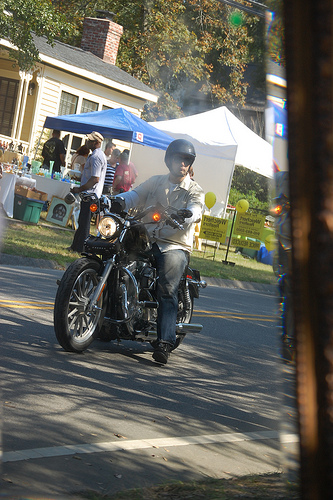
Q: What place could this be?
A: It is a yard.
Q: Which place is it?
A: It is a yard.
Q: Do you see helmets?
A: Yes, there is a helmet.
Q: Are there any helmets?
A: Yes, there is a helmet.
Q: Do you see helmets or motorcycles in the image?
A: Yes, there is a helmet.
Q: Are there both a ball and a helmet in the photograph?
A: No, there is a helmet but no balls.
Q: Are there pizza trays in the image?
A: No, there are no pizza trays.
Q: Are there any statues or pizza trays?
A: No, there are no pizza trays or statues.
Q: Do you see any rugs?
A: No, there are no rugs.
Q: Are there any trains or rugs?
A: No, there are no rugs or trains.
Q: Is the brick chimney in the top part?
A: Yes, the chimney is in the top of the image.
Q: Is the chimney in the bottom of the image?
A: No, the chimney is in the top of the image.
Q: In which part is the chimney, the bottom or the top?
A: The chimney is in the top of the image.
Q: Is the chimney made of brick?
A: Yes, the chimney is made of brick.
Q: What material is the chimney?
A: The chimney is made of brick.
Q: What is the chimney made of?
A: The chimney is made of brick.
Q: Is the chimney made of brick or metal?
A: The chimney is made of brick.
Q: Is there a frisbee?
A: No, there are no frisbees.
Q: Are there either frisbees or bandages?
A: No, there are no frisbees or bandages.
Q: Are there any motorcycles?
A: Yes, there is a motorcycle.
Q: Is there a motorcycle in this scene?
A: Yes, there is a motorcycle.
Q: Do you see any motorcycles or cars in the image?
A: Yes, there is a motorcycle.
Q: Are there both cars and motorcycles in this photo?
A: No, there is a motorcycle but no cars.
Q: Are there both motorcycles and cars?
A: No, there is a motorcycle but no cars.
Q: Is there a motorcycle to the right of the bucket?
A: Yes, there is a motorcycle to the right of the bucket.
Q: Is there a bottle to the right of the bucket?
A: No, there is a motorcycle to the right of the bucket.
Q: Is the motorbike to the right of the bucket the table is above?
A: Yes, the motorbike is to the right of the bucket.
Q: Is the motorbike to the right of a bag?
A: No, the motorbike is to the right of the bucket.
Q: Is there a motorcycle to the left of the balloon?
A: Yes, there is a motorcycle to the left of the balloon.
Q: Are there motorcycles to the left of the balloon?
A: Yes, there is a motorcycle to the left of the balloon.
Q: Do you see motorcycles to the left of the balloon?
A: Yes, there is a motorcycle to the left of the balloon.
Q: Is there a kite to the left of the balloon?
A: No, there is a motorcycle to the left of the balloon.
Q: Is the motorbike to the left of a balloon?
A: Yes, the motorbike is to the left of a balloon.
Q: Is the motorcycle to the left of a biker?
A: No, the motorcycle is to the left of a balloon.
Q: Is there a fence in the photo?
A: No, there are no fences.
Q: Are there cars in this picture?
A: No, there are no cars.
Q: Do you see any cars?
A: No, there are no cars.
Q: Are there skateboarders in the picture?
A: No, there are no skateboarders.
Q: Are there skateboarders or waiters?
A: No, there are no skateboarders or waiters.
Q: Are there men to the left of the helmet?
A: Yes, there is a man to the left of the helmet.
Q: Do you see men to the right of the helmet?
A: No, the man is to the left of the helmet.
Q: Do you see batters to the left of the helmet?
A: No, there is a man to the left of the helmet.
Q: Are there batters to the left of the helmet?
A: No, there is a man to the left of the helmet.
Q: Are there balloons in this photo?
A: Yes, there is a balloon.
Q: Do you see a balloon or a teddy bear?
A: Yes, there is a balloon.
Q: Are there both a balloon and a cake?
A: No, there is a balloon but no cakes.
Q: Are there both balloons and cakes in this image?
A: No, there is a balloon but no cakes.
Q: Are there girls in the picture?
A: No, there are no girls.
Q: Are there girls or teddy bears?
A: No, there are no girls or teddy bears.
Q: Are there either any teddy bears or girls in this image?
A: No, there are no girls or teddy bears.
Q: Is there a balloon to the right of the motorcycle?
A: Yes, there is a balloon to the right of the motorcycle.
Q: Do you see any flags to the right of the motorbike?
A: No, there is a balloon to the right of the motorbike.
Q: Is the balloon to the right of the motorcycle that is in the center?
A: Yes, the balloon is to the right of the motorbike.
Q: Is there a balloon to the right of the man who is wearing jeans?
A: Yes, there is a balloon to the right of the man.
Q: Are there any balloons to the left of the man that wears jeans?
A: No, the balloon is to the right of the man.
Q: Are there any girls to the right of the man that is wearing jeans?
A: No, there is a balloon to the right of the man.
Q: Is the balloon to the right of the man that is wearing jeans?
A: Yes, the balloon is to the right of the man.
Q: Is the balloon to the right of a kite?
A: No, the balloon is to the right of the man.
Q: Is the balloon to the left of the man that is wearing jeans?
A: No, the balloon is to the right of the man.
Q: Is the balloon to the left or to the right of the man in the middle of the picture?
A: The balloon is to the right of the man.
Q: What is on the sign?
A: The balloon is on the sign.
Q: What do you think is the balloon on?
A: The balloon is on the sign.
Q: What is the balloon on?
A: The balloon is on the sign.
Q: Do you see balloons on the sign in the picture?
A: Yes, there is a balloon on the sign.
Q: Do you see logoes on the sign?
A: No, there is a balloon on the sign.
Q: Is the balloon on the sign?
A: Yes, the balloon is on the sign.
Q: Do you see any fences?
A: No, there are no fences.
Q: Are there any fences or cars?
A: No, there are no fences or cars.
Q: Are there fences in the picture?
A: No, there are no fences.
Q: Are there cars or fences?
A: No, there are no fences or cars.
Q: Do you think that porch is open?
A: Yes, the porch is open.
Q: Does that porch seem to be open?
A: Yes, the porch is open.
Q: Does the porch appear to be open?
A: Yes, the porch is open.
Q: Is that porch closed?
A: No, the porch is open.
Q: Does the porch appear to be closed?
A: No, the porch is open.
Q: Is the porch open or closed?
A: The porch is open.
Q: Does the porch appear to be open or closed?
A: The porch is open.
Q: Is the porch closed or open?
A: The porch is open.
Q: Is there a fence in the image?
A: No, there are no fences.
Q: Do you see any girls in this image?
A: No, there are no girls.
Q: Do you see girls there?
A: No, there are no girls.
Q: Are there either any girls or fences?
A: No, there are no girls or fences.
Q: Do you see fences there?
A: No, there are no fences.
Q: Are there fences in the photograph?
A: No, there are no fences.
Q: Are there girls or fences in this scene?
A: No, there are no fences or girls.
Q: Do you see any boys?
A: No, there are no boys.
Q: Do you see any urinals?
A: No, there are no urinals.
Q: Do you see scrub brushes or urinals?
A: No, there are no urinals or scrub brushes.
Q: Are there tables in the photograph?
A: Yes, there is a table.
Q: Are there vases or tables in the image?
A: Yes, there is a table.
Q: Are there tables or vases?
A: Yes, there is a table.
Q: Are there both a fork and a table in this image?
A: No, there is a table but no forks.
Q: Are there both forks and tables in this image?
A: No, there is a table but no forks.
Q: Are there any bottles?
A: No, there are no bottles.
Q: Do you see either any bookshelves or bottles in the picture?
A: No, there are no bottles or bookshelves.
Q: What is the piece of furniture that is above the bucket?
A: The piece of furniture is a table.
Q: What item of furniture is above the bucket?
A: The piece of furniture is a table.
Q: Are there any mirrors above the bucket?
A: No, there is a table above the bucket.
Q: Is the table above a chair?
A: No, the table is above the bucket.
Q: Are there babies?
A: No, there are no babies.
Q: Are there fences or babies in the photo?
A: No, there are no babies or fences.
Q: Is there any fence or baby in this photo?
A: No, there are no babies or fences.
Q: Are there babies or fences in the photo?
A: No, there are no babies or fences.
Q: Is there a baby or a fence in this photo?
A: No, there are no babies or fences.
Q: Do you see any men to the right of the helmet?
A: No, the man is to the left of the helmet.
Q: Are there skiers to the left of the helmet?
A: No, there is a man to the left of the helmet.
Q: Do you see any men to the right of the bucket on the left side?
A: Yes, there is a man to the right of the bucket.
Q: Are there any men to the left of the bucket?
A: No, the man is to the right of the bucket.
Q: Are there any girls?
A: No, there are no girls.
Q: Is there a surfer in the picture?
A: No, there are no surfers.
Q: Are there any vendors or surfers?
A: No, there are no surfers or vendors.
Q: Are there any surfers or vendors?
A: No, there are no surfers or vendors.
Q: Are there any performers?
A: No, there are no performers.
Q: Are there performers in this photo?
A: No, there are no performers.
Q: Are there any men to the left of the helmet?
A: Yes, there is a man to the left of the helmet.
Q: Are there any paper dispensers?
A: No, there are no paper dispensers.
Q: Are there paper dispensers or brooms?
A: No, there are no paper dispensers or brooms.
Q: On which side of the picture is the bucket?
A: The bucket is on the left of the image.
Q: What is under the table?
A: The bucket is under the table.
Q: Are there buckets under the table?
A: Yes, there is a bucket under the table.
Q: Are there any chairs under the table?
A: No, there is a bucket under the table.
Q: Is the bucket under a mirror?
A: No, the bucket is under the table.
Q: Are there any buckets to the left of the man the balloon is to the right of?
A: Yes, there is a bucket to the left of the man.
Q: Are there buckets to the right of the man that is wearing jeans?
A: No, the bucket is to the left of the man.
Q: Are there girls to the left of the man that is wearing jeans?
A: No, there is a bucket to the left of the man.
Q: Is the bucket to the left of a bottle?
A: No, the bucket is to the left of a man.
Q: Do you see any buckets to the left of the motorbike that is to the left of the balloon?
A: Yes, there is a bucket to the left of the motorbike.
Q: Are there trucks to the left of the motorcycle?
A: No, there is a bucket to the left of the motorcycle.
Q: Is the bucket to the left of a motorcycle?
A: Yes, the bucket is to the left of a motorcycle.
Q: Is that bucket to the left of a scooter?
A: No, the bucket is to the left of a motorcycle.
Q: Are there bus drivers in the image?
A: No, there are no bus drivers.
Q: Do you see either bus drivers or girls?
A: No, there are no bus drivers or girls.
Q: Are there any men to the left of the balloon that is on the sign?
A: Yes, there is a man to the left of the balloon.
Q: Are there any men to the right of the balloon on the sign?
A: No, the man is to the left of the balloon.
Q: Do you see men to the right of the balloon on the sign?
A: No, the man is to the left of the balloon.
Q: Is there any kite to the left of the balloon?
A: No, there is a man to the left of the balloon.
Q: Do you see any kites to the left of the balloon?
A: No, there is a man to the left of the balloon.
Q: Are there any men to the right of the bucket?
A: Yes, there is a man to the right of the bucket.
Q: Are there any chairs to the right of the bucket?
A: No, there is a man to the right of the bucket.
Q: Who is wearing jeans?
A: The man is wearing jeans.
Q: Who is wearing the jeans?
A: The man is wearing jeans.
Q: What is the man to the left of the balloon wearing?
A: The man is wearing jeans.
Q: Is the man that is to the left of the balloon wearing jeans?
A: Yes, the man is wearing jeans.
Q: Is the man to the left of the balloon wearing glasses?
A: No, the man is wearing jeans.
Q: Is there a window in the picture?
A: Yes, there are windows.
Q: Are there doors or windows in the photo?
A: Yes, there are windows.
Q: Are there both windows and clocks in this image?
A: No, there are windows but no clocks.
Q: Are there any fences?
A: No, there are no fences.